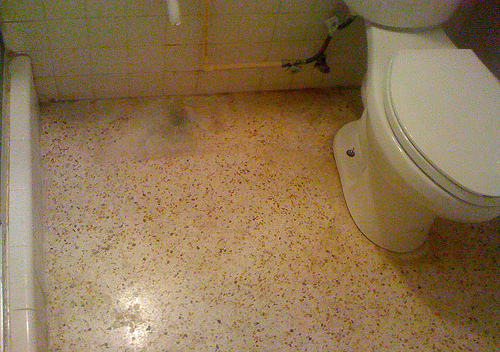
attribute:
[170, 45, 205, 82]
tile — white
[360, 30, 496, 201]
toilet — white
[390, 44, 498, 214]
toilet lid — white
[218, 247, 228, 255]
speck — brown 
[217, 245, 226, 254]
speck — brown 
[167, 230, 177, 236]
speck — brown 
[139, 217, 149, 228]
speck — brown 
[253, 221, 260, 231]
speck — brown 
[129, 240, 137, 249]
speck — brown 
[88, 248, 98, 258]
speck — brown 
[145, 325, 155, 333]
speck — brown 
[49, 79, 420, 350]
floor — brown 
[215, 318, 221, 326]
speck — brown 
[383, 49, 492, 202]
seat — closed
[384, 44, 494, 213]
seat — closed